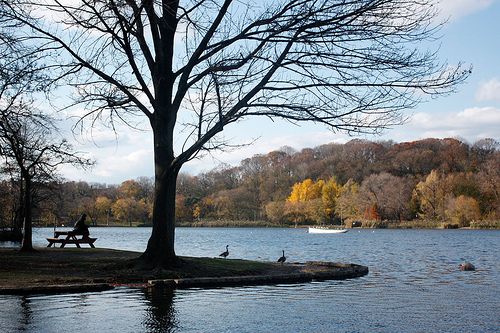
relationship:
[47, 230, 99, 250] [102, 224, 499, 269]
table by water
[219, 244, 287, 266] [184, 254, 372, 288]
birds on peninsula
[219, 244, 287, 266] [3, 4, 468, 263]
birds under tree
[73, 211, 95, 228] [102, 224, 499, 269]
person by water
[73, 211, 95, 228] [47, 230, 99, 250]
guy on bench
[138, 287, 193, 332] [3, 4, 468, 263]
reflection of tree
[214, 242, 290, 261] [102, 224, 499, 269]
birds near water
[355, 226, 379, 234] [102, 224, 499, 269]
birds on water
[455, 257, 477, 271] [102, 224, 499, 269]
object in water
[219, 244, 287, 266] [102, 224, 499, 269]
birds by water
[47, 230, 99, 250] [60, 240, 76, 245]
table of wood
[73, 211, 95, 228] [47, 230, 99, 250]
person on table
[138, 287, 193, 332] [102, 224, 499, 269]
reflection in water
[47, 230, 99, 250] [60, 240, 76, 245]
table made of wood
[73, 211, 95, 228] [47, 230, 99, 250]
person sitting on table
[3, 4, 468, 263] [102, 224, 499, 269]
tree by water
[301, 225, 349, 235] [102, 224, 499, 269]
boat on water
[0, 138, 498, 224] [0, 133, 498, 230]
forest in background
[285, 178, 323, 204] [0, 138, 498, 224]
tree of forest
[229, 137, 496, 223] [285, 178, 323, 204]
hill covered in tree